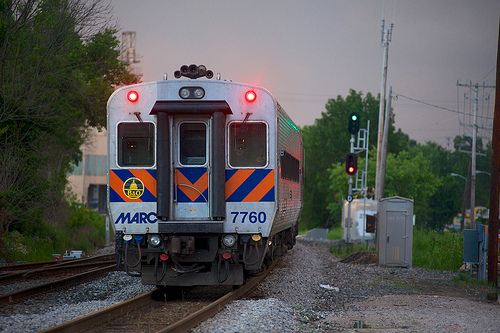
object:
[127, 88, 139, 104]
red lights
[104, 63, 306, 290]
train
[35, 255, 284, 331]
train track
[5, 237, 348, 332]
gravel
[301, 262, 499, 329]
ground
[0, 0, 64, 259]
trees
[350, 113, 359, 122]
green light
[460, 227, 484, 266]
electrical box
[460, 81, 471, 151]
phone lines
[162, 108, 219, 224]
door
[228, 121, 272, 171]
windows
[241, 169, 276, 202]
stripes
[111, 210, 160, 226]
marc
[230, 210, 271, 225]
numbers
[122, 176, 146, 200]
logo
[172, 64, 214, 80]
horn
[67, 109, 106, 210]
building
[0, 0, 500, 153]
sky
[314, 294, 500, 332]
water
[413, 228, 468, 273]
long grass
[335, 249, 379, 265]
pile of dirt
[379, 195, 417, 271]
small house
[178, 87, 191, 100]
lights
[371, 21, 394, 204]
pole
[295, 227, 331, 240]
road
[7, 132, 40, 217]
left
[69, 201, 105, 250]
bushes